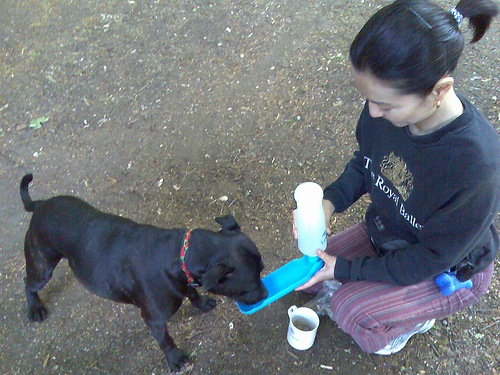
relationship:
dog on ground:
[14, 173, 265, 365] [1, 0, 498, 373]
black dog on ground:
[19, 172, 268, 373] [1, 0, 498, 373]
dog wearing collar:
[14, 173, 265, 365] [178, 225, 204, 289]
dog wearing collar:
[14, 173, 265, 365] [168, 222, 214, 301]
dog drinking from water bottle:
[14, 173, 265, 365] [234, 177, 329, 316]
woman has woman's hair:
[290, 1, 499, 356] [351, 7, 486, 110]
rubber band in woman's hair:
[446, 4, 478, 46] [351, 7, 486, 110]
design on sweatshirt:
[359, 146, 428, 233] [302, 99, 496, 289]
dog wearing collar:
[14, 173, 265, 365] [179, 229, 194, 291]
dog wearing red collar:
[14, 173, 265, 365] [177, 229, 188, 279]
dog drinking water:
[14, 173, 265, 365] [268, 263, 316, 298]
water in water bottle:
[268, 263, 316, 298] [234, 177, 329, 316]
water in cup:
[293, 315, 314, 330] [280, 301, 320, 349]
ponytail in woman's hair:
[425, 1, 487, 43] [351, 7, 486, 110]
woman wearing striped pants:
[290, 1, 499, 356] [312, 221, 497, 359]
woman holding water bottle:
[290, 1, 499, 356] [234, 177, 329, 316]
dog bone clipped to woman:
[434, 270, 474, 297] [290, 1, 499, 356]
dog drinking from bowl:
[14, 173, 265, 365] [235, 260, 317, 317]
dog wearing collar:
[14, 173, 265, 365] [170, 230, 205, 290]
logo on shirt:
[377, 150, 417, 202] [321, 101, 498, 287]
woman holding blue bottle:
[290, 1, 499, 356] [290, 183, 329, 258]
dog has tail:
[14, 173, 265, 365] [5, 158, 64, 228]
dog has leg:
[14, 173, 265, 365] [139, 304, 195, 374]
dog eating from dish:
[14, 173, 265, 365] [234, 250, 323, 314]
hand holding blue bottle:
[290, 210, 330, 235] [290, 183, 329, 258]